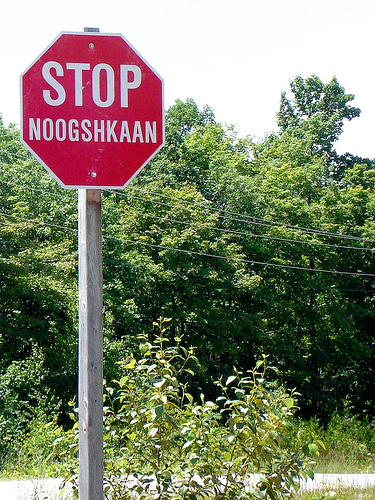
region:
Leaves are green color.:
[185, 273, 286, 314]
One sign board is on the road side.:
[20, 46, 163, 194]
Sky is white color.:
[164, 26, 339, 74]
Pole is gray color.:
[76, 195, 103, 493]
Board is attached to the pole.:
[19, 22, 164, 298]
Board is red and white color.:
[8, 31, 171, 187]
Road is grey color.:
[136, 470, 370, 496]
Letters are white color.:
[24, 58, 169, 163]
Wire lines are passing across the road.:
[19, 159, 354, 282]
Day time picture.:
[8, 17, 364, 490]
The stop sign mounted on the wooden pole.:
[12, 34, 169, 192]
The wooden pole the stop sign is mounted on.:
[72, 187, 114, 498]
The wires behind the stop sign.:
[6, 146, 374, 284]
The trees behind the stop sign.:
[5, 65, 374, 413]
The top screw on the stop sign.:
[84, 38, 99, 49]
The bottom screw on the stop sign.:
[85, 169, 102, 180]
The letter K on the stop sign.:
[105, 117, 118, 142]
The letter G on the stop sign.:
[66, 115, 82, 141]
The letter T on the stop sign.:
[61, 60, 91, 108]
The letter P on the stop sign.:
[118, 57, 144, 108]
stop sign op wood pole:
[15, 24, 148, 497]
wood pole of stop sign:
[60, 176, 130, 499]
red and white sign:
[19, 42, 184, 202]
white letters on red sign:
[31, 52, 155, 112]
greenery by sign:
[75, 357, 307, 498]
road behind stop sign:
[9, 457, 355, 491]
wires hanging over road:
[0, 167, 343, 234]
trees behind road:
[9, 159, 358, 426]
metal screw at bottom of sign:
[83, 165, 103, 176]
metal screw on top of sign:
[83, 32, 99, 49]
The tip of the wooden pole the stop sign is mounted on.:
[82, 20, 101, 34]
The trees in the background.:
[3, 30, 374, 400]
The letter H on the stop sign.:
[94, 117, 107, 142]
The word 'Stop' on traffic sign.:
[40, 63, 141, 113]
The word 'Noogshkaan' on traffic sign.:
[26, 115, 156, 145]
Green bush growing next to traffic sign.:
[49, 318, 322, 493]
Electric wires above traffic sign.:
[0, 148, 369, 285]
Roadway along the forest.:
[5, 473, 370, 497]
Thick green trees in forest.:
[0, 71, 372, 420]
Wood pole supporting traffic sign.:
[75, 188, 109, 492]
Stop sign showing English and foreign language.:
[18, 28, 168, 193]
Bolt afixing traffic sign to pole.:
[87, 42, 91, 48]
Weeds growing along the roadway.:
[279, 396, 373, 475]